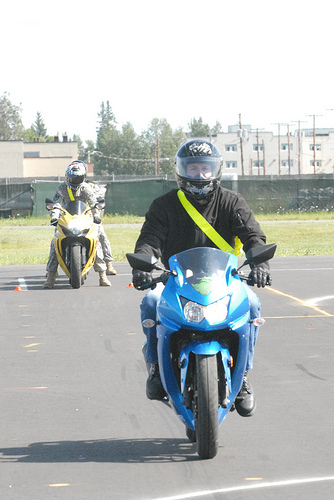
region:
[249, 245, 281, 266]
side mirror of the motorbike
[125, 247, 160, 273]
side mirror of the motorbike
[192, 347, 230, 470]
front wheel of motor bike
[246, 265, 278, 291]
a gloved hand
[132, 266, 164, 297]
a gloved hand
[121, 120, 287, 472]
man is riding a blue motor bike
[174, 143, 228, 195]
man is wearing helmet with visor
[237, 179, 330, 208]
fence covered in green tarp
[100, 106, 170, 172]
trees in the background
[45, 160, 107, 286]
man is riding yellow and black motor bike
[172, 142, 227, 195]
a person wearing a helmet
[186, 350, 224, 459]
tire on a motorcycle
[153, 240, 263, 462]
a blue motorcycle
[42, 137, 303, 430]
two motorcycles with riders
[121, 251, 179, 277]
a mirror on a motorcycle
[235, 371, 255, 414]
a person wearing a black boot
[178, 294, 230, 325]
headlight on a motorcycle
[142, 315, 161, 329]
directional indicator on a motorcycle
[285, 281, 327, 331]
pavement with painted lines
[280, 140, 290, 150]
a window on a building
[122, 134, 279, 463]
cyclist with a clear visor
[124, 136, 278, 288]
man with a yellow strap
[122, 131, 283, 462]
man with a runt motorcycle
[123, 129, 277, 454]
motorcycle with a useless windshield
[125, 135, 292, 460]
man in jacket and gloves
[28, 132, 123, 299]
two people riding in tandem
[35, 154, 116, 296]
two people wearing similar pants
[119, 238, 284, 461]
a cycle with dual headlights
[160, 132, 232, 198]
a helmet with an emblem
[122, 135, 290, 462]
motorcycle rider in jeans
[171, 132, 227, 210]
A MOTORCYCLE HELMUT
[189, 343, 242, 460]
FRONT MOTORCYCLE WHEEL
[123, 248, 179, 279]
SIDE VIEW MIRROR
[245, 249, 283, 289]
A BLACK LEATHER GLOVE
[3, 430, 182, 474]
A SHADOW ON THE PAVEMENT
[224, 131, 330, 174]
BUILDING IN THE BACKGROUND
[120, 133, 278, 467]
A MAN RIDING A BLUE MOTORCYCLE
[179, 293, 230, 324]
MOTORCYCLE HEADLIGHTS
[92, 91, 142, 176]
TREES IN THE BACKGROUND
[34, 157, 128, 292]
A PERSON ON A MOTORCYCLE IN THE BACKGROUND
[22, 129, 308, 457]
Three motorcycle riders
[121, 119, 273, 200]
One rider has a black helmet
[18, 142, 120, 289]
Motorcycle rider with passenger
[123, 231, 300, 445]
A blue motorcycle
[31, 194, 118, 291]
A yellow motorcycle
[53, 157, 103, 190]
A white motorcycle helmit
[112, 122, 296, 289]
Rider dressed in black jacket and gloves.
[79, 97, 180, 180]
Trees on the horizon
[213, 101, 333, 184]
A building in the distance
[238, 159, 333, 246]
Grass growing near a fence